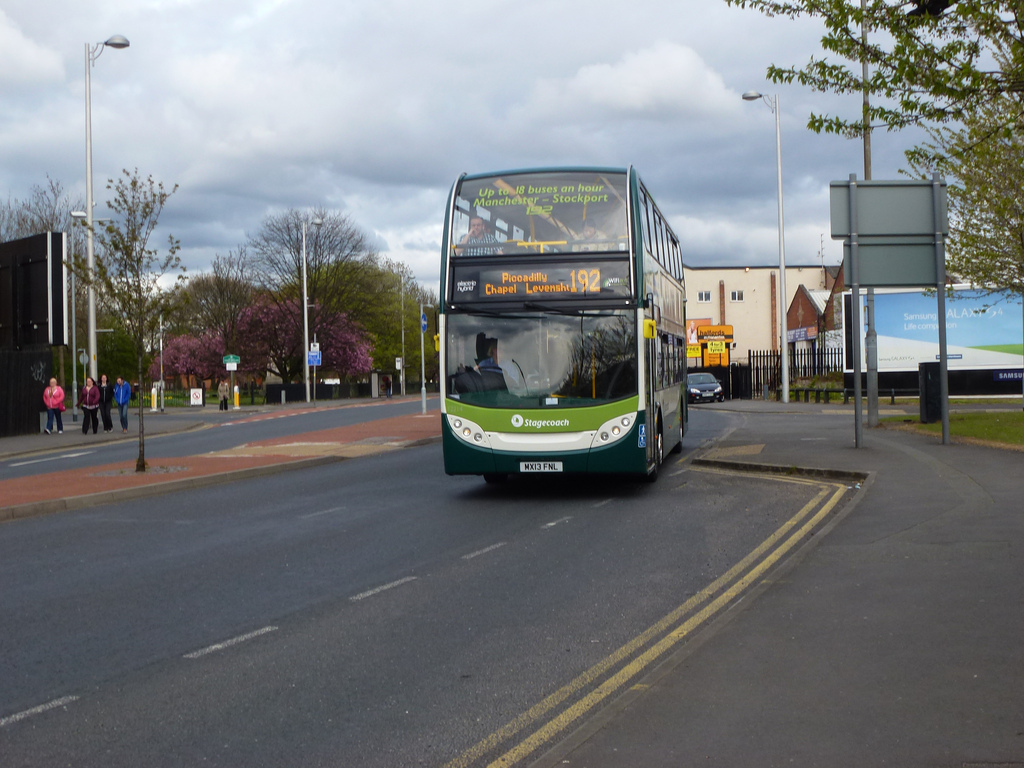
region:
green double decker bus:
[436, 164, 689, 485]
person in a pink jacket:
[41, 377, 67, 435]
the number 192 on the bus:
[566, 265, 604, 295]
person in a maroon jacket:
[76, 374, 102, 435]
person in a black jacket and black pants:
[92, 372, 115, 431]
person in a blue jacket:
[111, 374, 134, 433]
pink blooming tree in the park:
[145, 298, 263, 397]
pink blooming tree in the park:
[223, 295, 370, 394]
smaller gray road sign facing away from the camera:
[841, 237, 947, 289]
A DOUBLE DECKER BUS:
[427, 160, 699, 494]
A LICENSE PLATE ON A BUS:
[513, 456, 571, 483]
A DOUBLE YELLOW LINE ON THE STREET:
[440, 454, 859, 767]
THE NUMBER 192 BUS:
[427, 160, 694, 500]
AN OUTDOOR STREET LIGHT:
[737, 75, 795, 415]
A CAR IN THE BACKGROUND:
[680, 362, 731, 413]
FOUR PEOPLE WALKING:
[38, 366, 136, 443]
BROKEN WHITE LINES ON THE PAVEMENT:
[4, 513, 600, 730]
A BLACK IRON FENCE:
[689, 341, 845, 405]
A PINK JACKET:
[39, 382, 71, 415]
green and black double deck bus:
[396, 127, 700, 507]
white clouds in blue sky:
[379, 47, 434, 118]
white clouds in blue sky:
[224, 25, 308, 111]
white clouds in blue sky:
[309, 113, 385, 171]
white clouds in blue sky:
[176, 127, 233, 176]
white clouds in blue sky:
[222, 34, 327, 112]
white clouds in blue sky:
[347, 4, 462, 100]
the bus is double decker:
[414, 156, 702, 507]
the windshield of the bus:
[432, 309, 651, 415]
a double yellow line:
[571, 501, 781, 730]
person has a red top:
[37, 368, 72, 438]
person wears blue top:
[107, 375, 137, 436]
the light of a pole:
[72, 20, 139, 366]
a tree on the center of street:
[65, 160, 199, 514]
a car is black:
[682, 357, 730, 415]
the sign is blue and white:
[297, 322, 326, 409]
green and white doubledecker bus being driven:
[436, 159, 692, 489]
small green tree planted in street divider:
[63, 161, 194, 475]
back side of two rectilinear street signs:
[827, 174, 961, 449]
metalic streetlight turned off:
[299, 215, 329, 405]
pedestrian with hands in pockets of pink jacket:
[38, 374, 64, 438]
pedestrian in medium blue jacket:
[113, 370, 133, 434]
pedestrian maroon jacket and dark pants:
[75, 373, 104, 435]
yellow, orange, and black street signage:
[686, 317, 737, 368]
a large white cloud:
[514, 40, 748, 138]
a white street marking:
[454, 535, 518, 564]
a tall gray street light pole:
[740, 83, 799, 404]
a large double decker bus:
[444, 171, 680, 485]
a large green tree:
[285, 252, 419, 373]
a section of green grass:
[908, 407, 1022, 446]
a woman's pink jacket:
[43, 386, 67, 406]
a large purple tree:
[146, 335, 219, 378]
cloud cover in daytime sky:
[3, 4, 1018, 286]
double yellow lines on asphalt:
[456, 459, 864, 764]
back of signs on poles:
[832, 176, 954, 448]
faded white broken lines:
[5, 493, 613, 728]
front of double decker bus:
[434, 167, 685, 485]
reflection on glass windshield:
[451, 310, 644, 402]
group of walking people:
[43, 373, 139, 432]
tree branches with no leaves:
[247, 208, 384, 354]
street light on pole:
[81, 34, 129, 376]